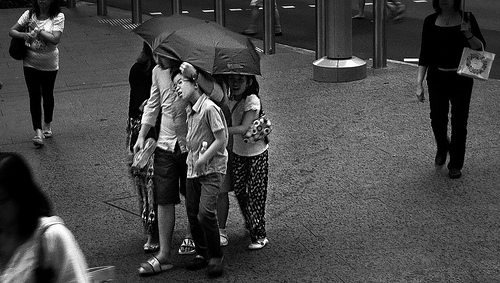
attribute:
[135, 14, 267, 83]
umbrella — black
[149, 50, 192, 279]
man — person, perso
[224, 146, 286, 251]
pants — polka dotted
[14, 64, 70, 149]
woman — walking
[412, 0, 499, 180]
woman — walking, person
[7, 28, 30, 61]
purse — black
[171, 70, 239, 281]
boy — light-skied, person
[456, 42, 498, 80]
paper bag — white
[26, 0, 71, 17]
hair — log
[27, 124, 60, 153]
shoe — white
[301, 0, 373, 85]
pillar — big, metal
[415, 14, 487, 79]
shirt — black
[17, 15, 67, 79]
shirt — white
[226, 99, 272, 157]
shirt — white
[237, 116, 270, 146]
bag — multicolored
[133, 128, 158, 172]
water bottle — large